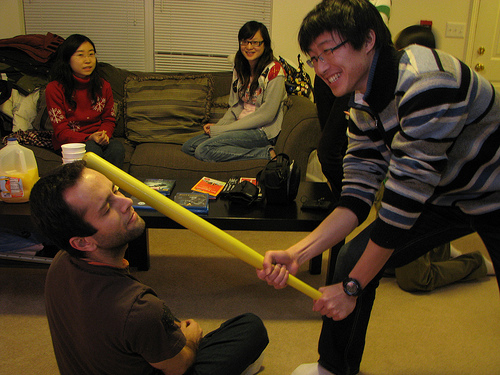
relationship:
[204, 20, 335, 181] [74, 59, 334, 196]
woman sitting on couch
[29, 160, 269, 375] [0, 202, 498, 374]
man on floor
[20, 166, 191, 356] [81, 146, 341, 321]
man hitting bat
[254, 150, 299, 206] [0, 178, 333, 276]
bag on coffee table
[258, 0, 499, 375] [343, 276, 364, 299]
man with watch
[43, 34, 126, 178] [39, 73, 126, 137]
woman wearing sweater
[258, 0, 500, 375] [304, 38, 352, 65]
man wearing glasses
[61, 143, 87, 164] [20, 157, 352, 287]
cups on table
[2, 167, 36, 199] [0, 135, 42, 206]
orange juice in carton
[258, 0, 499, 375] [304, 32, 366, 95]
man with face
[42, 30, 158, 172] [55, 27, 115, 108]
woman with hair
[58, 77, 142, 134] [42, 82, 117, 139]
sweater with snowflakes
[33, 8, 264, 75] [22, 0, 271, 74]
blinds on blinds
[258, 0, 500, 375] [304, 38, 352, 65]
man wears glasses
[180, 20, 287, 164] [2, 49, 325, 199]
woman sitting on couch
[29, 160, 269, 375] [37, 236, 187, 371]
man wearing shirt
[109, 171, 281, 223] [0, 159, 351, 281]
books scattered on a coffee table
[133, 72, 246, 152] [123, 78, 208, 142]
brown pillow with stripes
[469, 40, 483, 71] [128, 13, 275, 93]
lock on door